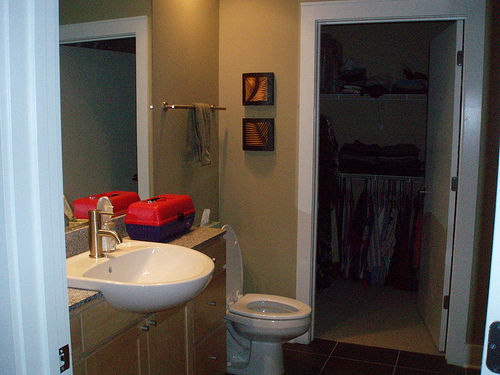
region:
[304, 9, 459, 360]
a walk-in closet is located off the bathroom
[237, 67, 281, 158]
pictures decorate the bathroom wall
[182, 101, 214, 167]
a hand towel hangs from the towel rack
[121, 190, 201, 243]
a red and blue carryall sits next to the sink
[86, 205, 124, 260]
the sink has gold fixtures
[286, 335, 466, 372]
the bathroom floor is set with dark tile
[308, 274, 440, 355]
the closet floor appears to be carpeted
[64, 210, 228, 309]
the counter top is patterned marble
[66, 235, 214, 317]
the sink juts out from the countertop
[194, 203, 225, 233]
a box of tissues sits on top of the toilet tank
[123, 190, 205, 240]
A red and black tool box.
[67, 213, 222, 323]
A white sink.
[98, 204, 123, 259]
A clear bottle of hand soap.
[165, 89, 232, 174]
A towel hanging from the towel rack.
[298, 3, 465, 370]
A white closet door.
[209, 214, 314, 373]
A white toilet in the bathroom.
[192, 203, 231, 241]
A tissue box on the back of the toilet.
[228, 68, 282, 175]
Two pictures on the wall.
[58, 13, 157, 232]
A mirror on the bathroom wall.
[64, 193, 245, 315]
The bathroom counter top.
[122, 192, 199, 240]
Blue and red box on the counter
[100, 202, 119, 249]
Soap bottle next to faucet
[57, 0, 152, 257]
Large mirror behind sink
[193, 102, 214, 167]
Gray towel above the toilet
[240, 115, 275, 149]
Small decor near the gray towel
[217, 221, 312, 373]
White toilet near white door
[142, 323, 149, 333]
Small knob below white sink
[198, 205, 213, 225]
White tissue paper below gray towel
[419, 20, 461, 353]
White door is opened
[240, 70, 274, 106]
Small decor above small decor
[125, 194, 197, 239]
a red and blue tackle box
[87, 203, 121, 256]
a gold sink faucet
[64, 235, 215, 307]
a white ceramic sink bowl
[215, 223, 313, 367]
toilet with lid up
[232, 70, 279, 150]
two framed feathers on wall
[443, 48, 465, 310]
hinges on a door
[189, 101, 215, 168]
towel on rack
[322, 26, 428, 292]
closet with clothes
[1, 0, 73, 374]
a white door leading to bathroom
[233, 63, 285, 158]
Two pictures hanging on the wall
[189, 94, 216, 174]
A green towel hanging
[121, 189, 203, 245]
A blue and red box on counter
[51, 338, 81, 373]
A door lock mechanism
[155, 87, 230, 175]
Towel rack with a towel on it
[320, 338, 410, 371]
Brown tile on the floor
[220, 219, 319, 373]
A white toilet in the bathroom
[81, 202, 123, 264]
A gold colored sink handle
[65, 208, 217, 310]
A large round sink in the bathroom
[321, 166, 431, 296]
Clothes hanging on the rack in closet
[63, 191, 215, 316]
plastic pink and purple box next to sink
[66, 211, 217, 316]
white sink has silver faucet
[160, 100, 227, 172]
towel on metal bar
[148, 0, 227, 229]
metal towel bar attached to beige painted wall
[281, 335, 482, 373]
floor is dark brown tiles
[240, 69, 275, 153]
square decor above square decor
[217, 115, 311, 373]
square black and orange decor above white toilet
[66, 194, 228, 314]
plastic box on counter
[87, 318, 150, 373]
metal knob on wooden cabinet